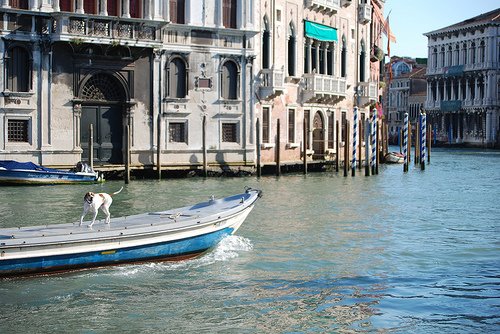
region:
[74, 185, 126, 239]
Dog on a boat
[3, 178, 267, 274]
Boat in the water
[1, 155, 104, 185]
Boat on the dock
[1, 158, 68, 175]
Blue tarp on the boat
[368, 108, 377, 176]
Blue and white pole in the water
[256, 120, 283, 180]
Two wooden poles in the water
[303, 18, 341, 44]
Blue awning on a building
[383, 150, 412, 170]
Boat between two wooden poles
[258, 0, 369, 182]
A pink building next to the water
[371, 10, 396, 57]
A flag on the side of the building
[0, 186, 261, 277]
blue and white boat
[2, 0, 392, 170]
building on water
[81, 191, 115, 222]
brown and white dog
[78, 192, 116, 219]
dog on blue and white boat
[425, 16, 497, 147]
big building in the right side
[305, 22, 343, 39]
aqua curtains on window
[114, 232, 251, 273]
little white wave in water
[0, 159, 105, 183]
blue and white boat in the door of building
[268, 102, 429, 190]
wooden fence on water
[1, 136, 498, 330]
large extension of water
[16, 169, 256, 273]
a blue and white boat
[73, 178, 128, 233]
a dog on a boat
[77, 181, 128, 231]
a tan and white dog on a boat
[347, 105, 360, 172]
blue and white strip pole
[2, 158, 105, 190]
a blue boat in the water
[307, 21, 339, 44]
a aqura sign over the door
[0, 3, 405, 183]
buildings on water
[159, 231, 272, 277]
a wave in front of the boat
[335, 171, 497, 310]
crystal clear waters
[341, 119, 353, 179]
a rust brown pole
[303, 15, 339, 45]
teal curtain over a balcony opening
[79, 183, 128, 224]
a white and brown dog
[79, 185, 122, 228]
a dog on a boat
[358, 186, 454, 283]
calm water in a canal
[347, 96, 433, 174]
a group of blue and white striped posts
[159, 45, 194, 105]
a decorative window on a wall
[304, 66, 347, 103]
white balcony railing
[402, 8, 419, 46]
a clear blue sky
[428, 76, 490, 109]
row of windows on a building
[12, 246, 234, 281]
blue bottom of a boat in the water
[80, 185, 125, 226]
a brown and white dog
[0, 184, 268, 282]
a dog on a boat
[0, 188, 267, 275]
a boat floating down a river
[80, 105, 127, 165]
a pair of dark double doors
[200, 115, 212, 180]
a wooden post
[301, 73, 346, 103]
a white balcony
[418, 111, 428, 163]
a white and blue stripped post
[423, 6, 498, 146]
a white building on the water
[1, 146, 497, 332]
water of the canal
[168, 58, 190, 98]
a boarded up window